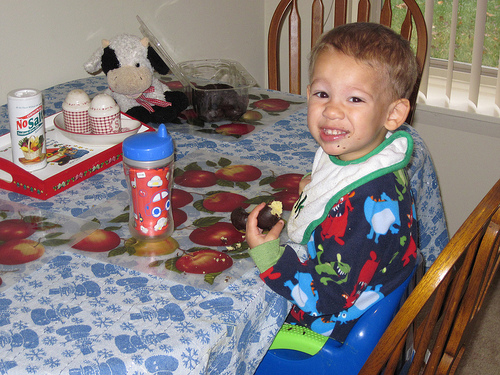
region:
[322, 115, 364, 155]
crumbs around the mouth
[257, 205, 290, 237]
the donut is half eaten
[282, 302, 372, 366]
the booster seat is blue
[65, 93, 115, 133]
shakers in the dish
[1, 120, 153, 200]
tray on the table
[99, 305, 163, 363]
the table cloth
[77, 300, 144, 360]
the table cloth is blue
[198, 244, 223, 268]
apple on the table mat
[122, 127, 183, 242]
a sippy cup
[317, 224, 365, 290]
boy is wearing a sleeper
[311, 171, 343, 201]
a bib the baby is wearing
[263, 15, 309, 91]
a chair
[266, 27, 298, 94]
the chair is brown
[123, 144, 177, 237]
the sippy cup is red and blue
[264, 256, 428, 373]
a blue and green booster seat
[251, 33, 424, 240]
a boy holding a donut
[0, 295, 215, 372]
a blue and white table cloth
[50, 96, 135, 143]
a red and white set of shakers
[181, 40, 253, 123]
a plastic container of donuts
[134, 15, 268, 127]
a plastic container with the lid open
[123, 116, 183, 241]
a plastic sip cup with a blue lid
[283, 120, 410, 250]
a young boy wearing a bib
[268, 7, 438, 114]
a wood chair at a table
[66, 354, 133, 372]
blue snowman on table cloth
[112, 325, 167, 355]
blue snowman on table cloth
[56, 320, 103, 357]
blue snowman on table cloth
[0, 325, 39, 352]
blue snowman on table cloth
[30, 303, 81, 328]
blue snowman on table cloth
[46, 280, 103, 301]
blue snowman on table cloth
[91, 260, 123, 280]
blue snowman on table cloth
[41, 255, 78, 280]
blue snowman on table cloth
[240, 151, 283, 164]
blue snowman on table cloth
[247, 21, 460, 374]
this is a baby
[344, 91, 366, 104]
this is an eye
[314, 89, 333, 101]
this is an eye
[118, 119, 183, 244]
this is a milk bottle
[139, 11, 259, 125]
this is a tin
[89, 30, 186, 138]
this is a doll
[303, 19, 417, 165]
this is a head of a baby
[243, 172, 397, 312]
this is a hand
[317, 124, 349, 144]
these are teeth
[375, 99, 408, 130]
this is an ear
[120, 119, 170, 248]
this is a feeding bottle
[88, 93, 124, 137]
this is a feeding bottle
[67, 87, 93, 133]
this is a feeding bottle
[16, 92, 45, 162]
this is baby food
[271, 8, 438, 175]
head of the kid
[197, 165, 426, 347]
clothing on the boy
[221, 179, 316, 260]
food in kid's hand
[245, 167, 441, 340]
drawings of monsters on outfit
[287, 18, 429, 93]
hair on kid's head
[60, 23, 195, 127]
stuffed animal on table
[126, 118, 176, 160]
blue top thermos on the table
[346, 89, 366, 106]
small brown eye left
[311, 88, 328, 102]
small brown eye right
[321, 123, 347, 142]
small child's mouth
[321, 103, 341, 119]
small child's nose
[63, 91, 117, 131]
small bottles on the table